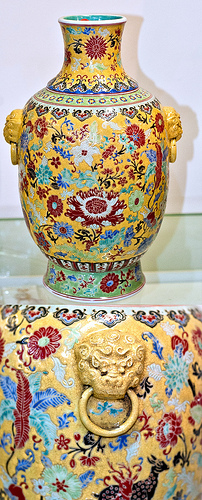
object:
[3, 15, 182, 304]
vase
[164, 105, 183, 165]
yellow emblem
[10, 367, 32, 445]
red feather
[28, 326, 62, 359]
flower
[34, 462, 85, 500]
flower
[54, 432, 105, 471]
vine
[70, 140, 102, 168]
flower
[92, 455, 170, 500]
deer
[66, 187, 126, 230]
red and white flower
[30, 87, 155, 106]
pattern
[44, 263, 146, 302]
base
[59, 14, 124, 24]
opening